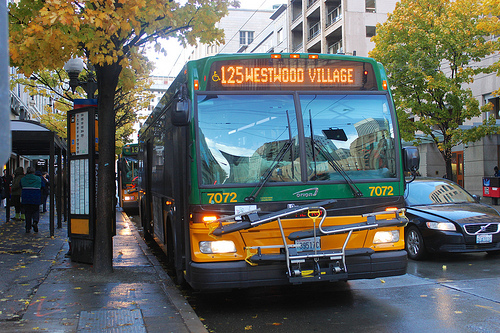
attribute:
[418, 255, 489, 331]
road — paved, black, crowded, wet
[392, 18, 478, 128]
tree — full, lush, yellow, orange, green, brown, close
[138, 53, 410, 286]
bus — clean, dry, green, black, large, moving, close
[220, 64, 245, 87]
number 125 — orange, black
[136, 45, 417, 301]
bus — green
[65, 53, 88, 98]
street light — not on